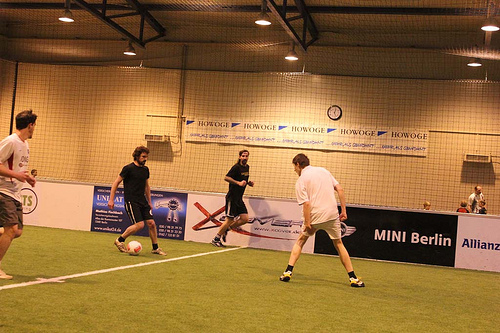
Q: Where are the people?
A: On an inside court.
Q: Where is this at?
A: Soccer field.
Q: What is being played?
A: Soccer.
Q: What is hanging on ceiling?
A: Lights.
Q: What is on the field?
A: White line.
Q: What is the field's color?
A: Green.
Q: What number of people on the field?
A: 4.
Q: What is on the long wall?
A: Advertisements.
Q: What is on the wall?
A: Banner.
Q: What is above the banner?
A: Clock.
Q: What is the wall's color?
A: White.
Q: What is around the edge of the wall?
A: Advertisements.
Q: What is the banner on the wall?
A: White and blue.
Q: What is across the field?
A: White lines.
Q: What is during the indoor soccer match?
A: Four soccer players.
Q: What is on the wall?
A: Advertising banner.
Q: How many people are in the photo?
A: Eight.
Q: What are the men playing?
A: Soccer.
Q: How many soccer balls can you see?
A: One.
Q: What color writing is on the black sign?
A: White.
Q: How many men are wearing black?
A: Two.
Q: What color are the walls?
A: White.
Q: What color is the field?
A: Green.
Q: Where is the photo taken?
A: In a arena.